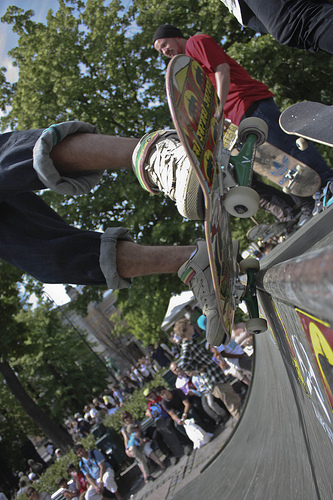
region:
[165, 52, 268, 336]
Upclose of a skateboard.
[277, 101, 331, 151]
The black top of a skateboard.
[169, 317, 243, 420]
A guy standing with hands on hips and khaki pants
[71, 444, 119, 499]
A guy in a blue shirt wearing a backpack sitting down.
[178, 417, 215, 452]
A large white bag a guy in black that is sitting is holding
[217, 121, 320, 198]
A brown dirty skateboard with an ADIDAS symbol on the bottom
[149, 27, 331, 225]
Guy in a black beanie and red shirt.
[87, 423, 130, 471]
A green newspaper dispenser by a guy in a blue shirt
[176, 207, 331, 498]
A gray skateboard ramp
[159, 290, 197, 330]
A white pointy tent in the background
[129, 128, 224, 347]
Tennis shoes with colorful straps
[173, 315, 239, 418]
Young man in a plaid shirt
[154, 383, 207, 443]
Man in black t shirt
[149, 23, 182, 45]
Black knitted beanie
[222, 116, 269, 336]
Wheels of a skateboard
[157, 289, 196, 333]
White roof of a gazebo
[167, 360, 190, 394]
Bald man in a purple shirt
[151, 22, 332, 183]
Young man in red t shirt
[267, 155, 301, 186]
Adidas logo in light blue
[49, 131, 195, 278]
Man's shins that are hairy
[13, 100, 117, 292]
Man wearing pants rolled up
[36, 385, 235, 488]
Group of people watching skateboarders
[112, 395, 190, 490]
Woman holding her son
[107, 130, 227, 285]
Man wearing tennis shoes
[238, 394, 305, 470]
Scratches on the ramp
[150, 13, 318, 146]
Man wearing a red tshirt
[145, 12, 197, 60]
Man wearing a black beanie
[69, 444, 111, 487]
Man sitting on the bench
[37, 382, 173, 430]
Group of people standing together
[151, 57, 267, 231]
Bottom of skateboard has a pattern on it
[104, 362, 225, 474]
people sitting on a bench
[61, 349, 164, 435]
group of people standing up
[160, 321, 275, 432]
young man standing by the ramp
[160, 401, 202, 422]
elbows resting on knees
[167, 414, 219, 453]
large white bag between the legs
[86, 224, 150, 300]
bottom of pants are rolled up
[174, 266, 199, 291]
green, yellow, and red stripes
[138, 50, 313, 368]
skateboard on a ramp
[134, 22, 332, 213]
man standing with a skateboard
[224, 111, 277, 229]
two white wheels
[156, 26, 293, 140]
this man is in a red shirt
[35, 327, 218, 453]
there is a group of people attending this event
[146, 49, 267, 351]
this person is on a skateboard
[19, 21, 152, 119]
there are trees in the background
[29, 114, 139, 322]
the mans pants legs are rolled up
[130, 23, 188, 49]
the man is wearing a black beanie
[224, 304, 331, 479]
this is a skate ramp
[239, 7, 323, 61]
this person is wearing black pants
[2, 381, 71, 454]
this is a tree trunk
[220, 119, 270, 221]
a pair of the skateboards wheels